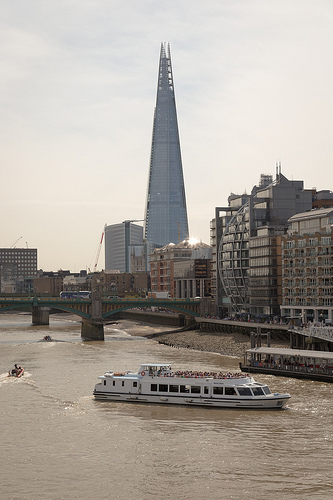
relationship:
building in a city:
[146, 37, 191, 265] [13, 172, 331, 362]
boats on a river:
[92, 363, 291, 408] [6, 317, 181, 455]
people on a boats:
[171, 366, 254, 381] [92, 363, 291, 408]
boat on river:
[7, 361, 30, 385] [6, 317, 181, 455]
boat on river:
[43, 332, 57, 346] [6, 317, 181, 455]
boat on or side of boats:
[242, 342, 331, 376] [92, 363, 291, 408]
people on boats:
[171, 366, 254, 381] [92, 363, 291, 408]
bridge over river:
[2, 288, 208, 340] [6, 317, 181, 455]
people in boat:
[13, 362, 21, 371] [7, 361, 30, 385]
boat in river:
[7, 361, 30, 385] [6, 317, 181, 455]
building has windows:
[274, 226, 332, 317] [293, 247, 324, 279]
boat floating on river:
[7, 361, 30, 385] [6, 317, 181, 455]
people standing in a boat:
[13, 362, 21, 371] [7, 361, 30, 385]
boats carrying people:
[92, 363, 291, 408] [171, 366, 254, 381]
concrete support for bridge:
[78, 317, 108, 345] [2, 288, 208, 340]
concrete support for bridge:
[31, 307, 56, 326] [2, 288, 208, 340]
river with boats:
[6, 317, 181, 455] [9, 334, 333, 418]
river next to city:
[6, 317, 181, 455] [13, 172, 331, 362]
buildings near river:
[8, 243, 330, 316] [6, 317, 181, 455]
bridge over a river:
[2, 288, 208, 340] [6, 317, 181, 455]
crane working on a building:
[93, 226, 107, 271] [102, 221, 145, 279]